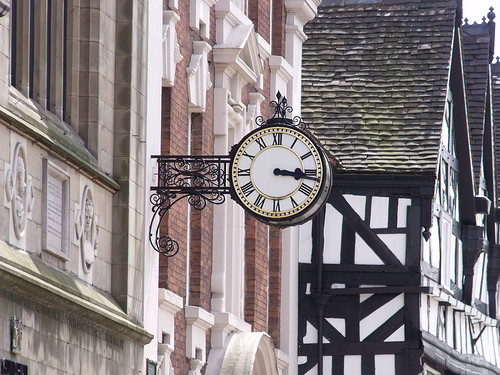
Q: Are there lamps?
A: No, there are no lamps.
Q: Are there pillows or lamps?
A: No, there are no lamps or pillows.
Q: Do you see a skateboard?
A: No, there are no skateboards.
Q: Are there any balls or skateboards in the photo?
A: No, there are no skateboards or balls.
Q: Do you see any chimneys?
A: No, there are no chimneys.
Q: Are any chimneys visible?
A: No, there are no chimneys.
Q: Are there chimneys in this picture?
A: No, there are no chimneys.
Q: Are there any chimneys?
A: No, there are no chimneys.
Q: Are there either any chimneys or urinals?
A: No, there are no chimneys or urinals.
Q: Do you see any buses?
A: No, there are no buses.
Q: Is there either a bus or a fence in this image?
A: No, there are no buses or fences.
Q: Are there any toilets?
A: No, there are no toilets.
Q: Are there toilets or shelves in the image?
A: No, there are no toilets or shelves.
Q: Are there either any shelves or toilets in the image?
A: No, there are no toilets or shelves.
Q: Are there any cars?
A: No, there are no cars.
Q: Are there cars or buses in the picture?
A: No, there are no cars or buses.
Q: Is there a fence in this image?
A: No, there are no fences.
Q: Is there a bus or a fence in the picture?
A: No, there are no fences or buses.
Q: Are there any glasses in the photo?
A: No, there are no glasses.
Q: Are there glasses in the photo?
A: No, there are no glasses.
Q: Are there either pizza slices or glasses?
A: No, there are no glasses or pizza slices.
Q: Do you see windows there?
A: Yes, there are windows.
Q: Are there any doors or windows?
A: Yes, there are windows.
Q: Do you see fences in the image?
A: No, there are no fences.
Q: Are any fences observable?
A: No, there are no fences.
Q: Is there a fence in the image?
A: No, there are no fences.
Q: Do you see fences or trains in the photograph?
A: No, there are no fences or trains.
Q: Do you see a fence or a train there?
A: No, there are no fences or trains.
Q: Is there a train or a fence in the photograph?
A: No, there are no fences or trains.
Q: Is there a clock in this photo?
A: Yes, there is a clock.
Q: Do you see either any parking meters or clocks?
A: Yes, there is a clock.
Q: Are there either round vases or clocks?
A: Yes, there is a round clock.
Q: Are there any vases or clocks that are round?
A: Yes, the clock is round.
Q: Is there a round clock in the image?
A: Yes, there is a round clock.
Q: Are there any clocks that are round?
A: Yes, there is a clock that is round.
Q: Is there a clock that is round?
A: Yes, there is a clock that is round.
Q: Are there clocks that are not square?
A: Yes, there is a round clock.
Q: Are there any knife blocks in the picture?
A: No, there are no knife blocks.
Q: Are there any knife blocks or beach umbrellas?
A: No, there are no knife blocks or beach umbrellas.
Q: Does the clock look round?
A: Yes, the clock is round.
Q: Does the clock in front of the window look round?
A: Yes, the clock is round.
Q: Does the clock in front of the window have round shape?
A: Yes, the clock is round.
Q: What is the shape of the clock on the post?
A: The clock is round.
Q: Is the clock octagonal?
A: No, the clock is round.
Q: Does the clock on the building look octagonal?
A: No, the clock is round.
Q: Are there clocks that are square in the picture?
A: No, there is a clock but it is round.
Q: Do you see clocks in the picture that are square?
A: No, there is a clock but it is round.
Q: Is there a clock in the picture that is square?
A: No, there is a clock but it is round.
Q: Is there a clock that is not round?
A: No, there is a clock but it is round.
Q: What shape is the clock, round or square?
A: The clock is round.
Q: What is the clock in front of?
A: The clock is in front of the window.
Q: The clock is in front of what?
A: The clock is in front of the window.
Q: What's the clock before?
A: The clock is in front of the window.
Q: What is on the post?
A: The clock is on the post.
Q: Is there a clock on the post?
A: Yes, there is a clock on the post.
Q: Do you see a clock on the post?
A: Yes, there is a clock on the post.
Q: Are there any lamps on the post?
A: No, there is a clock on the post.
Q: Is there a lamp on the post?
A: No, there is a clock on the post.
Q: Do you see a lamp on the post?
A: No, there is a clock on the post.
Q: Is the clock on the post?
A: Yes, the clock is on the post.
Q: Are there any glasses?
A: No, there are no glasses.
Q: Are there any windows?
A: Yes, there is a window.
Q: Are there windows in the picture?
A: Yes, there is a window.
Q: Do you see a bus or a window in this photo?
A: Yes, there is a window.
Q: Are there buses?
A: No, there are no buses.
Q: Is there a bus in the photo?
A: No, there are no buses.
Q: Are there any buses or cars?
A: No, there are no buses or cars.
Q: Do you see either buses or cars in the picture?
A: No, there are no buses or cars.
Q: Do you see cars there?
A: No, there are no cars.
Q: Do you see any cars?
A: No, there are no cars.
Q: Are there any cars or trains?
A: No, there are no cars or trains.